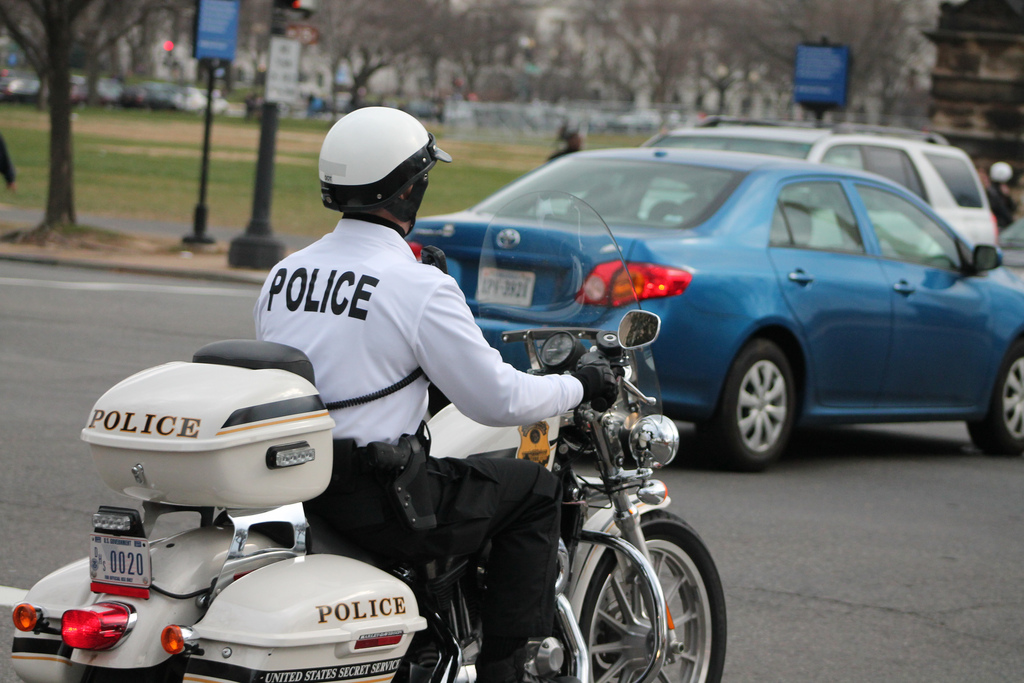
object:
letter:
[328, 267, 355, 317]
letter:
[266, 263, 288, 309]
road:
[6, 254, 1021, 680]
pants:
[305, 442, 572, 682]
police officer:
[246, 98, 618, 680]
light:
[569, 258, 705, 313]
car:
[414, 142, 1022, 476]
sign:
[188, 2, 237, 61]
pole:
[184, 53, 220, 241]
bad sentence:
[940, 498, 963, 510]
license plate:
[77, 532, 164, 603]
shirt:
[255, 214, 584, 529]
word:
[247, 251, 388, 329]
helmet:
[306, 96, 463, 203]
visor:
[402, 124, 468, 183]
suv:
[633, 100, 1017, 345]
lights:
[49, 598, 134, 655]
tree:
[8, 0, 156, 237]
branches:
[1, 13, 57, 86]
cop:
[247, 100, 588, 683]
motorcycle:
[0, 306, 731, 683]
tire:
[555, 509, 732, 683]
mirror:
[611, 301, 661, 352]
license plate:
[471, 261, 543, 311]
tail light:
[577, 251, 695, 313]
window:
[767, 167, 868, 263]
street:
[2, 175, 178, 683]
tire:
[719, 337, 806, 470]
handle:
[781, 260, 825, 295]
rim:
[737, 357, 794, 470]